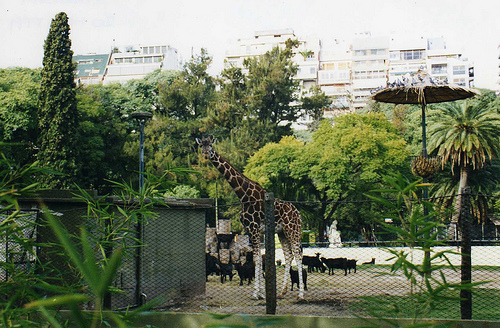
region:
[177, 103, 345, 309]
the giraffe is looking at the camera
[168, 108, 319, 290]
the giraffe is tall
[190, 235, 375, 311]
the goats are black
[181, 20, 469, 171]
the building is behind the trees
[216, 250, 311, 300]
under the knees are white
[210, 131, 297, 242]
the giraffe is tan and brown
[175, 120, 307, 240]
the giraffe has brown spots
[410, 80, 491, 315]
a palm tree to the right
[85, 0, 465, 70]
the sky is overcast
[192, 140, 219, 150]
the eyes are black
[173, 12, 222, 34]
this is the sky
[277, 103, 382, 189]
this is a tree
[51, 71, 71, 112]
the leaves are green in color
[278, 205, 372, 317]
this is a fence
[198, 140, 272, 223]
this is a giraffe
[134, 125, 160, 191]
this is a pole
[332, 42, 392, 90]
this is a building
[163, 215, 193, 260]
this is the wall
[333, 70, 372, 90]
the wall is brown in color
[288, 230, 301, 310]
this is the leg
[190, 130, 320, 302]
A giraffe behind a fence.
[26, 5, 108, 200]
A tall green tree.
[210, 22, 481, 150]
A set of large multi story buildings.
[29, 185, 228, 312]
A small shed structure.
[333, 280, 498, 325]
green grass near a giraffe.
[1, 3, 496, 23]
a section of hazy gray sky.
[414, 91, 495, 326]
a palm tree.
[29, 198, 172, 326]
a green leafy plant.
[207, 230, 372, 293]
a herd of animals near a giraffe.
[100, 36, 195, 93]
a tall multi story building.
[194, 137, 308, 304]
Giraffe looking directly at camera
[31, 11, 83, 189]
Tall thin tree with thick covering of leaves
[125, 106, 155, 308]
Outdoor lamp on tall metal pole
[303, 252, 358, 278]
Small group of black goats in animal enclosure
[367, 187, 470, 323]
Several thin green plants with sparse leaves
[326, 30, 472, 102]
Background building with multitude of windows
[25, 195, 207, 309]
Shed or outdoor enclosure of some sort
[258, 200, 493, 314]
Metal chain-link fence supported by wooden poles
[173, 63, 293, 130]
Cluster of trees with green leaves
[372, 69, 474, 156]
Straw umbrellas on black metal pole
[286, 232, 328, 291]
part of a fence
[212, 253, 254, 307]
part of a fence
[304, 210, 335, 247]
part of a fence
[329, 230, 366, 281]
part of a fence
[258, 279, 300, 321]
part of a fecne